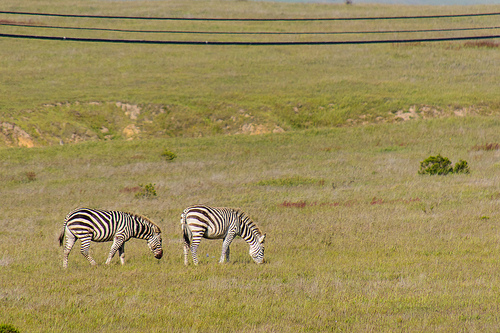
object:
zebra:
[181, 205, 266, 264]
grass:
[52, 152, 335, 178]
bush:
[419, 155, 470, 175]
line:
[0, 11, 500, 21]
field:
[0, 68, 500, 203]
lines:
[0, 34, 499, 46]